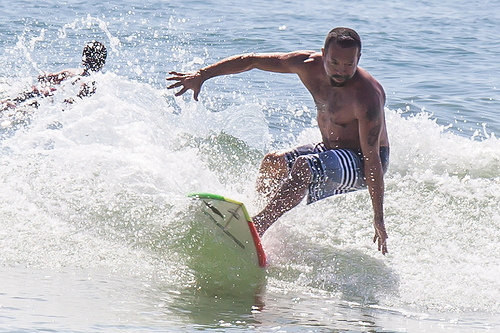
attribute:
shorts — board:
[277, 136, 399, 222]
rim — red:
[247, 217, 268, 264]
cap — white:
[17, 71, 498, 231]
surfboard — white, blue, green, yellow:
[186, 192, 269, 284]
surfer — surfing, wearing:
[160, 26, 396, 255]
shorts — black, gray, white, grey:
[284, 140, 370, 217]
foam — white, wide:
[7, 37, 499, 318]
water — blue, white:
[1, 3, 499, 332]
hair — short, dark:
[324, 25, 365, 63]